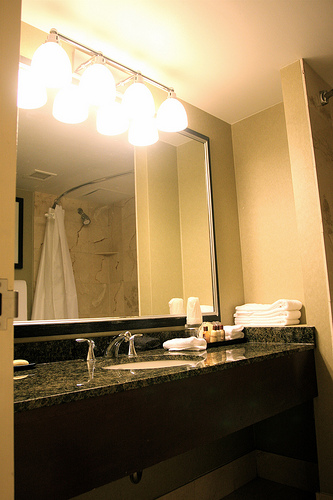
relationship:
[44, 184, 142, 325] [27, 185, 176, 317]
walls of shower stall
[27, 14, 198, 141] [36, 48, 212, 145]
row of lights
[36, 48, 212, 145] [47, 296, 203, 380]
lights above sink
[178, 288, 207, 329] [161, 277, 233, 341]
stack of cups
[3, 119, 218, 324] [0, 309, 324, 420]
mirror above counter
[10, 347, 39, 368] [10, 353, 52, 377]
soap in dish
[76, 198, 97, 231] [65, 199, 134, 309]
shower head on wall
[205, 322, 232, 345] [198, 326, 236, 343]
bottles of toiletries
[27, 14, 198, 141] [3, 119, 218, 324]
lights over mirror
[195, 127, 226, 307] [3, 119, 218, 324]
silver edge of mirror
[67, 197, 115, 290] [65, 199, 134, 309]
shower on wall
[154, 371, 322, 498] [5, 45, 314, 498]
dark in bathroom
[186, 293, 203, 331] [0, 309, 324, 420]
air freshener on counter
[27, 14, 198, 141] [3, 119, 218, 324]
lights above mirror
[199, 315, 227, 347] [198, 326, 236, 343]
samples of toiletries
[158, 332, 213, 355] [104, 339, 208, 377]
washcloth beside sink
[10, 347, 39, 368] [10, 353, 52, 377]
soap on dish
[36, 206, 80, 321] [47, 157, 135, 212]
curtain on rod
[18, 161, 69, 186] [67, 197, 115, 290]
vent above shower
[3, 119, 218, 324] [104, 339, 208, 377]
mirror above sink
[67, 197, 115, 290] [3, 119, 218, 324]
shower reflection in mirror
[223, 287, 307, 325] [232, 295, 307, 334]
white bath towel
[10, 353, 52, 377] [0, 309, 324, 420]
soap dish on counter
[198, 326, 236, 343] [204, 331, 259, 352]
toiletries on tray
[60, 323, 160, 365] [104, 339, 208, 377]
fixtures on sink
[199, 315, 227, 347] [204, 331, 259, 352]
shampoo on tray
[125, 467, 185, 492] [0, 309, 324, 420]
pipe under counter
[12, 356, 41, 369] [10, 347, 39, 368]
bar of soap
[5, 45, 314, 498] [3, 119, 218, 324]
room's reflection in mirror